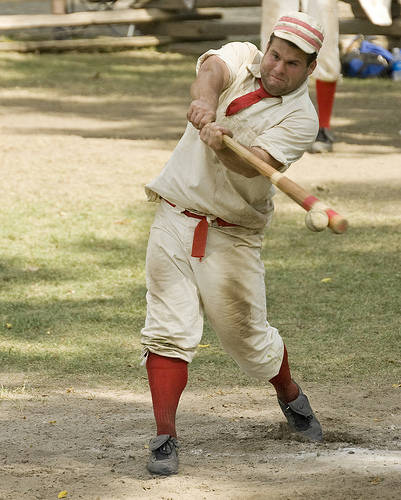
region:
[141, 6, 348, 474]
a base ball player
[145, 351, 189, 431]
a red sock on a leg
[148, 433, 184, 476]
a black shoe on a foot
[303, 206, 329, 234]
a white baseball in the air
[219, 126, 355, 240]
a wooden ball bat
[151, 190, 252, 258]
a red belt in pants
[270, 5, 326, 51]
a red and white hat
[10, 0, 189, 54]
a wooden log fence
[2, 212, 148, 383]
a shadow on the ground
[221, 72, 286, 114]
a red tie around a neck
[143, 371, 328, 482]
Man wearing shoes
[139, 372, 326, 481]
Man is wearing shoes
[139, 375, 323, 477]
Man wearing black shoes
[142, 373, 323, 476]
Man is wearing black shoes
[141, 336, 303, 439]
Man wearing socks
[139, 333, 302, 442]
Man is wearing socks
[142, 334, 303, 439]
Man wearing red socks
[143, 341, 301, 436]
Man is wearing red socks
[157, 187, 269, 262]
Man wearing a red belt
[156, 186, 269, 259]
Man is wearing a red belt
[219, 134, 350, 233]
A brown, white and red baseball bat.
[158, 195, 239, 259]
A red belt on a man batting.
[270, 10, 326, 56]
A white hat with red stripes on it.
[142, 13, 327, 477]
A man in a white and red uniform batting.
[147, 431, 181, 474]
A solid black dirty cleat on a man's right foot.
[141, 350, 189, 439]
A large red sock on a man's right leg.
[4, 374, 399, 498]
Brown dirt all around a batter.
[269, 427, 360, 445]
A dark hole at a batters left foot.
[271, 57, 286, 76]
Nose on the face of a player.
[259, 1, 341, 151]
White pants, red socks and black cleats on another player behind this one.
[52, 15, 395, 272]
a man playing baseball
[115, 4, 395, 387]
a man in a baseball uniform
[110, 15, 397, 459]
a man standing inside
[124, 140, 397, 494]
a man standing on a field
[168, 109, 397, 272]
a man hitting a ball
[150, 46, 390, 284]
a man hitting a baseball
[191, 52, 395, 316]
a man swinging a bat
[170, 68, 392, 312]
a man swinging a wooden bat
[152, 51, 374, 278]
a man swinging a baseball bat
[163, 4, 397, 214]
a man wearing a hat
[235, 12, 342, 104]
head of the man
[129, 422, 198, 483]
foot of the man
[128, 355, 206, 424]
red sock on the man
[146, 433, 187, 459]
laces on the foot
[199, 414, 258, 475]
dirt on the ground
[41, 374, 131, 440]
shadow on the ground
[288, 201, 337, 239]
ball on the bat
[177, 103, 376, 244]
man holding a bat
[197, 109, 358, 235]
brown bat in photo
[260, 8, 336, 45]
red stripes on the hat